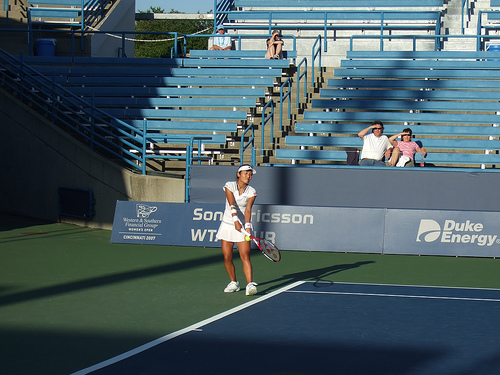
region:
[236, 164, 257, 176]
white visor on a tennis player's head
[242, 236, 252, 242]
tennis ball in a woman's hand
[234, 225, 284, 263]
red black and white tennis racket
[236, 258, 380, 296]
shadow on a tennis court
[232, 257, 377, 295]
female tennis player's shadow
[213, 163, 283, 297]
female tennis player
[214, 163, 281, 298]
ball and racket in a player's hand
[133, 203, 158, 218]
white graphic on a blue wall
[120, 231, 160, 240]
white text on a blue wall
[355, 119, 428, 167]
two people sitting in the stands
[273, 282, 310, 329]
part of a court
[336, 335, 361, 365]
part of a shade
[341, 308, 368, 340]
part pof a court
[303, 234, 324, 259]
part of a banner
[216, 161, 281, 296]
asian woman playing tennis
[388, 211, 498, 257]
blue colred duke energy sign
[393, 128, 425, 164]
woman in a pink shirt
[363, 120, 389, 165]
man in a white shirt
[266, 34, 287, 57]
man in a black shirt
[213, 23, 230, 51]
man in a blue hat and shirt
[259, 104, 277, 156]
blue hand rail on stairs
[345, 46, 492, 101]
blue audience bleachers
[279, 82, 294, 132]
blue hand rails on stairs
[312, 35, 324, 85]
blue hand rails on stair raILS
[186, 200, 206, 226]
The letter is white.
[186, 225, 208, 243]
The letter is white.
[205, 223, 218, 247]
The letter is white.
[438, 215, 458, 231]
The letter is white.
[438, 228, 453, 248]
The letter is white.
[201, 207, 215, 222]
The letter is white.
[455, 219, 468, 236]
The letter is white.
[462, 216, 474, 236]
The letter is white.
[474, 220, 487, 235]
The letter is white.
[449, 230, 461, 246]
The letter is white.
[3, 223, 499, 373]
back section of a blue and green tennis court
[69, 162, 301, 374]
woman standing behind a white line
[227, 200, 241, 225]
two white objects around woman's right arm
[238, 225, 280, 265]
woman holding a ball and a tennis racket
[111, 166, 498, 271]
dull blue wall at edge of court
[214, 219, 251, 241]
woman wearing a white tennis skirt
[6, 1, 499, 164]
blue bench seating in the audience area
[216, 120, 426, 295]
man and woman looking towards tennis player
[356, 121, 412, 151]
man and woman shading their eyes with their right hands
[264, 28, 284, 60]
person sitting with their knees drawn up